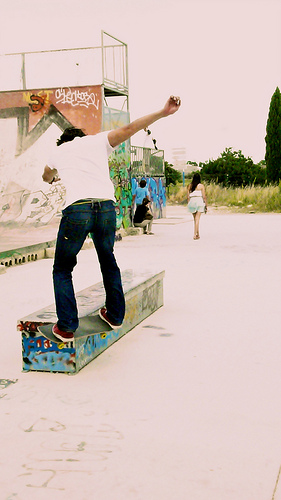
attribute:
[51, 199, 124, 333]
jeans — blue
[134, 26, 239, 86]
clouds — white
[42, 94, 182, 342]
man — skateboarding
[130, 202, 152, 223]
shirt — black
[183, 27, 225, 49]
clouds — white 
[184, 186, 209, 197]
shirt — white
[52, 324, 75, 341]
sneakers — red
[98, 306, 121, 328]
sneakers — red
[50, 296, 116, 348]
shoes — red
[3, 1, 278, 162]
sky — blue 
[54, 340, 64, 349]
wheel — yellow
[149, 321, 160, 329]
stain — black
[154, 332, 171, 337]
stain — black